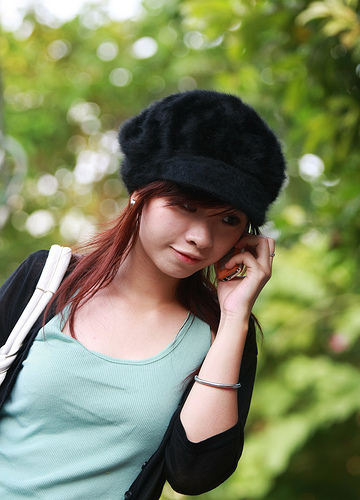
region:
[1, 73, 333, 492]
Young girl on a cell phone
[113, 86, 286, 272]
Black hat on the girls head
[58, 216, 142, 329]
red hair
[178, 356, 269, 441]
silver bracelet on an arm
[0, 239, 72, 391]
handbag strap over the shoulder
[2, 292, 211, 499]
turqouise t shirt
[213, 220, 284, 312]
cell phone in a hand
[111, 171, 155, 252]
gold earring on an ear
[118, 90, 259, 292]
young girl smiling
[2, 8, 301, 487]
young girl in front of green foliage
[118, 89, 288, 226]
a black fur hat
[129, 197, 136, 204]
a diamond stud earring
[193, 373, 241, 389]
a bracelet on the girls wrist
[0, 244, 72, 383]
a white leather purse strap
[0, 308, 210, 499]
the girl is wearing a green blouse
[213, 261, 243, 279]
an orange colored cell phone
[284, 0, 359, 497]
green trees and plants behind the girl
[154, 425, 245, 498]
the girl is wearing a black sweater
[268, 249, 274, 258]
the girl is wearing a ring on her middle finger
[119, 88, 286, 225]
a black rabbit fur hat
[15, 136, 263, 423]
one woman is talking in phone.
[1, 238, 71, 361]
Woman is carrying a bag in shoulder.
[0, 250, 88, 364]
Bag handle is white color.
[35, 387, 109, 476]
Inner shirt color is green.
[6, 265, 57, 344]
Woman is wearing black shirt.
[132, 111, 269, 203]
Woman is wearing black cap.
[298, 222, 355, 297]
leaves are green color.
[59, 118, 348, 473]
trees are behind the woman.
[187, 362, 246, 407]
Bangle is grey color.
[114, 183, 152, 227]
Woman is wearing earring.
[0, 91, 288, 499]
Attractive young woman talking on phone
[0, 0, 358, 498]
Green foliage behind woman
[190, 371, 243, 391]
Metal bracelet on woman's arm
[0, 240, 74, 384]
white handbag strap hanging from woman's shoulder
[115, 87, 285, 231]
Fluffy black hat on woman's head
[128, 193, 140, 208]
Bright metallic earing on woman's ear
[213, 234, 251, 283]
Small orange cell phone on woman's hand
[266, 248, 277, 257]
Silver ring on woman's finger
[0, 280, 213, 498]
Light blue shirt on woman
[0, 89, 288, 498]
Asian woman with brown hair wearing black and blue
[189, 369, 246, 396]
Girl's silver bracelet on her wrist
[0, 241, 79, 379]
White handle of a bag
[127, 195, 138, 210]
Bright silver earring in woman's hair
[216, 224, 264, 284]
Orange and silver cellphone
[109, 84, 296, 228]
Furry black hat with brim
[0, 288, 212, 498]
Light green tank top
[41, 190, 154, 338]
Strands of red hair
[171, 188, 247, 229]
Pair of woman's eyes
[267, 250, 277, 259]
Ring on woman's finger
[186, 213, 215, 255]
Woman's nose in the center of her face